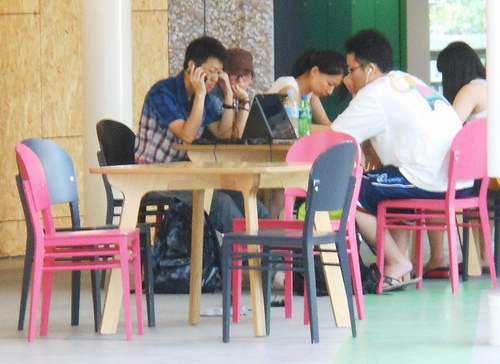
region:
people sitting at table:
[143, 26, 472, 262]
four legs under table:
[104, 168, 343, 331]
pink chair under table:
[228, 129, 360, 315]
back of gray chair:
[300, 137, 364, 214]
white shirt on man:
[342, 76, 460, 192]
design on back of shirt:
[395, 67, 442, 119]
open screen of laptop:
[252, 89, 305, 145]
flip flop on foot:
[374, 261, 426, 299]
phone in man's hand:
[181, 48, 223, 95]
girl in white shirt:
[278, 44, 348, 106]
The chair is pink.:
[13, 142, 148, 344]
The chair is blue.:
[211, 133, 358, 357]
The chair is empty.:
[9, 142, 152, 348]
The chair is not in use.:
[208, 132, 366, 351]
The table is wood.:
[81, 151, 358, 342]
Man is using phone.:
[131, 31, 238, 168]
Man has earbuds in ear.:
[320, 21, 476, 296]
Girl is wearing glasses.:
[220, 45, 272, 147]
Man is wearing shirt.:
[319, 24, 479, 310]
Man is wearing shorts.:
[318, 22, 478, 301]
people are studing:
[108, 14, 490, 223]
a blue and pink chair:
[4, 125, 151, 356]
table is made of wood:
[79, 145, 354, 339]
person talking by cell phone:
[128, 29, 242, 179]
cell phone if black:
[177, 51, 213, 97]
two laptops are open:
[231, 84, 308, 156]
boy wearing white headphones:
[336, 25, 433, 141]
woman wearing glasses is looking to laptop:
[219, 46, 281, 134]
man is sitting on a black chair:
[77, 29, 227, 166]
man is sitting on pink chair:
[337, 23, 494, 297]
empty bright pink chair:
[2, 123, 158, 349]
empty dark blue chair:
[200, 132, 384, 352]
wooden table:
[75, 133, 383, 351]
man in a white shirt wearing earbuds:
[300, 24, 490, 311]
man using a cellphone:
[108, 14, 240, 289]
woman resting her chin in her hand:
[225, 43, 270, 151]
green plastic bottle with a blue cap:
[290, 88, 327, 154]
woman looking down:
[228, 22, 353, 154]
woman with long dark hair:
[415, 19, 497, 194]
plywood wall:
[0, 2, 176, 283]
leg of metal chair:
[291, 265, 330, 347]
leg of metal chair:
[211, 276, 237, 351]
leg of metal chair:
[326, 279, 356, 336]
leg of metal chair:
[430, 233, 470, 293]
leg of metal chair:
[473, 240, 499, 288]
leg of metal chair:
[112, 287, 140, 343]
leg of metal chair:
[26, 290, 46, 342]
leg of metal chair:
[134, 291, 151, 332]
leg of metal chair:
[145, 290, 162, 323]